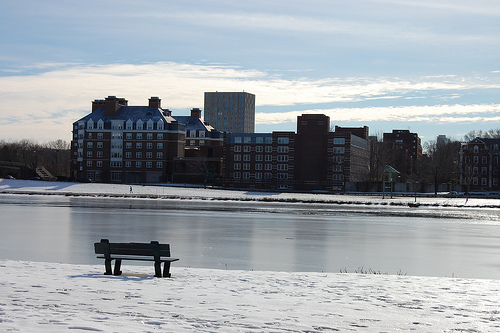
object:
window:
[154, 117, 165, 137]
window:
[276, 135, 290, 144]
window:
[470, 143, 480, 159]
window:
[125, 115, 135, 129]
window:
[232, 138, 240, 145]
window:
[480, 174, 491, 185]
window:
[123, 159, 133, 169]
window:
[261, 161, 272, 172]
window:
[480, 167, 493, 181]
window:
[465, 153, 471, 165]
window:
[333, 144, 345, 153]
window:
[111, 157, 123, 168]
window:
[97, 120, 106, 131]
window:
[254, 133, 265, 143]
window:
[469, 152, 481, 166]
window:
[467, 162, 478, 172]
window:
[277, 152, 290, 162]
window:
[197, 126, 208, 137]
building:
[68, 89, 223, 183]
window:
[74, 146, 85, 158]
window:
[254, 160, 264, 172]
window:
[482, 164, 493, 176]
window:
[480, 166, 489, 176]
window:
[232, 161, 239, 171]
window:
[111, 129, 124, 140]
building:
[223, 109, 422, 201]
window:
[143, 138, 154, 151]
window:
[273, 160, 291, 171]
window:
[464, 165, 470, 177]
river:
[6, 200, 496, 290]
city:
[64, 88, 498, 199]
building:
[432, 133, 496, 197]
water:
[300, 220, 490, 260]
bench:
[93, 239, 178, 277]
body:
[463, 199, 493, 211]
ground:
[3, 314, 80, 331]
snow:
[432, 286, 468, 302]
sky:
[20, 46, 57, 75]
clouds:
[266, 73, 493, 105]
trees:
[21, 144, 56, 188]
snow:
[72, 315, 135, 330]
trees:
[402, 150, 449, 199]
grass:
[331, 267, 410, 274]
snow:
[199, 307, 231, 315]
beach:
[200, 268, 234, 291]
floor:
[406, 294, 446, 314]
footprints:
[72, 274, 180, 300]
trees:
[0, 142, 21, 176]